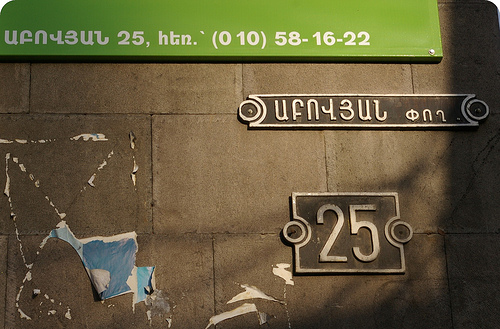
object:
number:
[315, 203, 347, 263]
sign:
[0, 0, 445, 63]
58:
[274, 31, 301, 46]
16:
[312, 31, 335, 46]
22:
[343, 31, 370, 46]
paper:
[45, 215, 159, 313]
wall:
[2, 3, 498, 326]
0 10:
[236, 30, 260, 45]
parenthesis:
[211, 30, 218, 49]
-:
[337, 38, 344, 42]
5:
[349, 204, 382, 262]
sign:
[280, 191, 414, 276]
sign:
[237, 92, 493, 131]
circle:
[239, 99, 262, 121]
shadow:
[24, 4, 499, 328]